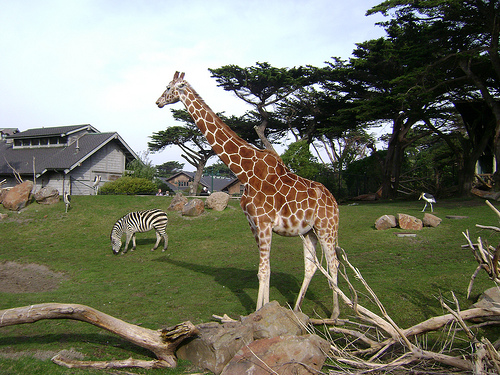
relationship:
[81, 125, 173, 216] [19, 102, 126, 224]
wall on building